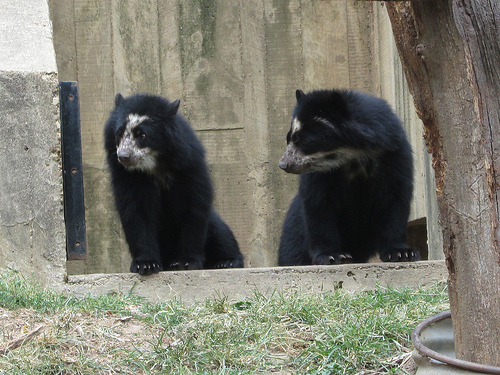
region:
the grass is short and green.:
[53, 305, 383, 373]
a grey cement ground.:
[3, 256, 455, 308]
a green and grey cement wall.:
[163, 4, 313, 81]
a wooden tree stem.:
[381, 0, 499, 373]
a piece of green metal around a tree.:
[408, 296, 482, 373]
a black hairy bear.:
[266, 79, 432, 267]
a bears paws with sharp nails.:
[378, 237, 427, 269]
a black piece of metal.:
[56, 77, 96, 275]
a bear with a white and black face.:
[93, 87, 188, 184]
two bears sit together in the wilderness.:
[66, 50, 437, 300]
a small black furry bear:
[278, 86, 417, 270]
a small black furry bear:
[110, 90, 245, 277]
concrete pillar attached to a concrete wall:
[0, 0, 66, 309]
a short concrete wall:
[64, 259, 469, 306]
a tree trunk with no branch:
[375, 0, 497, 372]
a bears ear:
[161, 98, 186, 115]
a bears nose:
[118, 150, 133, 165]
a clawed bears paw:
[376, 243, 418, 263]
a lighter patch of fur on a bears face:
[116, 113, 156, 173]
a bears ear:
[292, 89, 304, 104]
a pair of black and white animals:
[98, 90, 423, 270]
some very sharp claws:
[133, 263, 170, 273]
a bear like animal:
[98, 85, 250, 274]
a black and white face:
[106, 90, 187, 177]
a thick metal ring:
[409, 302, 498, 374]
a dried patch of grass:
[3, 300, 124, 369]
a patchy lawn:
[148, 295, 407, 374]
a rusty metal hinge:
[53, 78, 98, 264]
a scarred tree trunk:
[401, 25, 498, 359]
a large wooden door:
[46, 0, 421, 272]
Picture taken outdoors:
[45, 40, 455, 356]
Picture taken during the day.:
[52, 38, 441, 310]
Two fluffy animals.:
[86, 42, 422, 298]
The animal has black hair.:
[98, 78, 231, 280]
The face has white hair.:
[122, 116, 149, 163]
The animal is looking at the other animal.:
[264, 87, 368, 170]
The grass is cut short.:
[31, 282, 313, 374]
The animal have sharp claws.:
[135, 253, 208, 276]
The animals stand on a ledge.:
[118, 241, 408, 277]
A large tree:
[416, 41, 497, 308]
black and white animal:
[278, 88, 416, 263]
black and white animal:
[104, 90, 241, 269]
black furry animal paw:
[378, 241, 417, 261]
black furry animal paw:
[313, 246, 353, 263]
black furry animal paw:
[214, 258, 246, 269]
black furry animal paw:
[164, 258, 206, 271]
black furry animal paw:
[129, 260, 159, 275]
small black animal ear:
[166, 95, 180, 109]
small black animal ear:
[112, 93, 124, 105]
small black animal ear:
[295, 88, 308, 99]